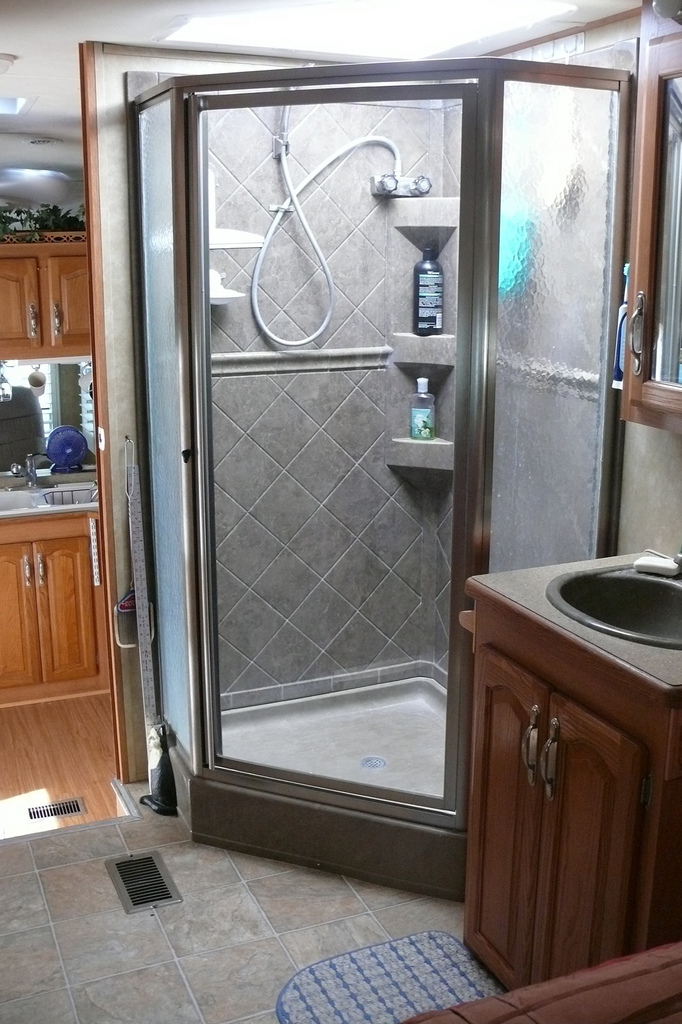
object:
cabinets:
[0, 510, 97, 686]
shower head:
[252, 87, 434, 347]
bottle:
[413, 244, 443, 335]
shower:
[134, 57, 631, 901]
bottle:
[409, 378, 435, 441]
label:
[412, 408, 435, 440]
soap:
[634, 558, 680, 578]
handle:
[523, 704, 542, 787]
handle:
[540, 717, 558, 800]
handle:
[37, 553, 45, 588]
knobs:
[382, 173, 399, 192]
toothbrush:
[612, 263, 630, 391]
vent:
[105, 851, 184, 916]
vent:
[28, 799, 87, 821]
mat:
[276, 931, 507, 1019]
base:
[459, 551, 682, 991]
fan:
[46, 425, 88, 472]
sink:
[0, 482, 99, 518]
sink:
[546, 568, 682, 651]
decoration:
[140, 725, 178, 816]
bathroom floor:
[0, 688, 510, 1024]